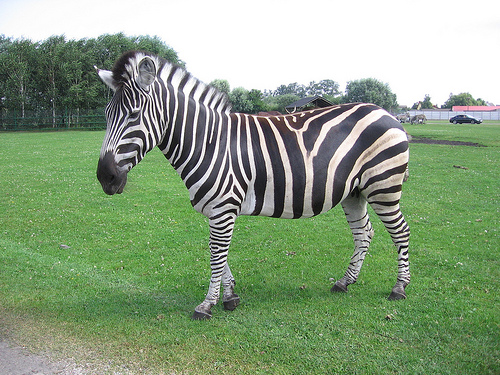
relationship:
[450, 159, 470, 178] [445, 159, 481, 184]
pile of excrement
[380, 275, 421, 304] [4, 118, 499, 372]
hoof on ground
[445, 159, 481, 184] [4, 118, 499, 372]
excrement on ground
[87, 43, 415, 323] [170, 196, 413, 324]
zebra has four legs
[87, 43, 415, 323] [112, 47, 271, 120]
zebra has mane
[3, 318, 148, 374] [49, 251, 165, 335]
path beside grass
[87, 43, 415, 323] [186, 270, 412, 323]
zebra has four hooves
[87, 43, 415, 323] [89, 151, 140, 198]
zebra has black nose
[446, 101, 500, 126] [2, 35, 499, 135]
building in background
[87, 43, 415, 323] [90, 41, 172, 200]
zebra has large head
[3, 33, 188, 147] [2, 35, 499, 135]
trees are in background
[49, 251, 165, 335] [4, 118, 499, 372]
grass on ground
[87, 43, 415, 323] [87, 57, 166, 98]
zebra has ears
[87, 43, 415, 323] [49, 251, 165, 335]
zebra on grass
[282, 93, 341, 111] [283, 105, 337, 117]
black roof on building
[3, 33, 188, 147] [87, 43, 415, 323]
trees are behind zebra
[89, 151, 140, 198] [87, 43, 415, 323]
black nose on zebra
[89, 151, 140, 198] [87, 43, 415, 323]
black nose of zebra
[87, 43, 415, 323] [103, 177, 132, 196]
zebra has mouth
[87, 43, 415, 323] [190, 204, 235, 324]
zebra has front left leg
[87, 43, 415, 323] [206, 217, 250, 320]
zebra has right leg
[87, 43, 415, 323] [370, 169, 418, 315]
zebra has back left leg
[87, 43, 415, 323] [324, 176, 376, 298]
zebra has back right leg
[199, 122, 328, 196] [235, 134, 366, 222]
stripes are on stomach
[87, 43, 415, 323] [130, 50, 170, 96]
zebra has left ear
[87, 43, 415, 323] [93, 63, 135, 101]
zebra has right ear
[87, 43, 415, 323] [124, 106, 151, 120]
zebra has eye